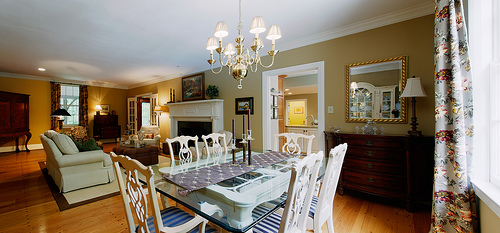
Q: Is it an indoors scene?
A: Yes, it is indoors.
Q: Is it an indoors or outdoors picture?
A: It is indoors.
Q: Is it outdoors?
A: No, it is indoors.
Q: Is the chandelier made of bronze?
A: Yes, the chandelier is made of bronze.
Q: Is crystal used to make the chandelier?
A: No, the chandelier is made of bronze.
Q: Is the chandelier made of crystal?
A: No, the chandelier is made of bronze.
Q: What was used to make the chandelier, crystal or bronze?
A: The chandelier is made of bronze.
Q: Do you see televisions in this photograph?
A: No, there are no televisions.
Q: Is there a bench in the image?
A: No, there are no benches.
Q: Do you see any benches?
A: No, there are no benches.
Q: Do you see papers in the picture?
A: No, there are no papers.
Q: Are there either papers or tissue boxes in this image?
A: No, there are no papers or tissue boxes.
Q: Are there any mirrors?
A: Yes, there is a mirror.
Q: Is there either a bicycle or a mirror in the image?
A: Yes, there is a mirror.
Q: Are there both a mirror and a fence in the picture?
A: No, there is a mirror but no fences.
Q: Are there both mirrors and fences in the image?
A: No, there is a mirror but no fences.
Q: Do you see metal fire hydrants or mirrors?
A: Yes, there is a metal mirror.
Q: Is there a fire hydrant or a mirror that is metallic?
A: Yes, the mirror is metallic.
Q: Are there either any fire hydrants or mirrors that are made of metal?
A: Yes, the mirror is made of metal.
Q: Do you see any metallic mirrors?
A: Yes, there is a metal mirror.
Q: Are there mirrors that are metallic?
A: Yes, there is a mirror that is metallic.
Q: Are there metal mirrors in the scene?
A: Yes, there is a mirror that is made of metal.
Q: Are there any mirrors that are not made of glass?
A: Yes, there is a mirror that is made of metal.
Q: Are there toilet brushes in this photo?
A: No, there are no toilet brushes.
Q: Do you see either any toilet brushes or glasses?
A: No, there are no toilet brushes or glasses.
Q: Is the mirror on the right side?
A: Yes, the mirror is on the right of the image.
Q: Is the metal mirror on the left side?
A: No, the mirror is on the right of the image.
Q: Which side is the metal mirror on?
A: The mirror is on the right of the image.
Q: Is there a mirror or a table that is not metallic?
A: No, there is a mirror but it is metallic.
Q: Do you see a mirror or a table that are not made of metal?
A: No, there is a mirror but it is made of metal.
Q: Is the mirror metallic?
A: Yes, the mirror is metallic.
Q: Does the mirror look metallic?
A: Yes, the mirror is metallic.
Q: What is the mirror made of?
A: The mirror is made of metal.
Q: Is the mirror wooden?
A: No, the mirror is metallic.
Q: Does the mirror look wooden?
A: No, the mirror is metallic.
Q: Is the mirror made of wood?
A: No, the mirror is made of metal.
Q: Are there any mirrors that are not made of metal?
A: No, there is a mirror but it is made of metal.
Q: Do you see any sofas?
A: Yes, there is a sofa.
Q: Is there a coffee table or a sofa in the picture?
A: Yes, there is a sofa.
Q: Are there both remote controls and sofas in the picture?
A: No, there is a sofa but no remote controls.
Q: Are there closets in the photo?
A: No, there are no closets.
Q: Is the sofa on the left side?
A: Yes, the sofa is on the left of the image.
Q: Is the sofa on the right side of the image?
A: No, the sofa is on the left of the image.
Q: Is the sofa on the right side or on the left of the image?
A: The sofa is on the left of the image.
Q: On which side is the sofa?
A: The sofa is on the left of the image.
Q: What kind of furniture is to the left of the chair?
A: The piece of furniture is a sofa.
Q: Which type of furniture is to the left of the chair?
A: The piece of furniture is a sofa.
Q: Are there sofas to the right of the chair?
A: No, the sofa is to the left of the chair.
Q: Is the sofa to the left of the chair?
A: Yes, the sofa is to the left of the chair.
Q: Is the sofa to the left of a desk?
A: No, the sofa is to the left of the chair.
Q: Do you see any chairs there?
A: Yes, there is a chair.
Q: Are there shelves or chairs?
A: Yes, there is a chair.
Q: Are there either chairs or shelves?
A: Yes, there is a chair.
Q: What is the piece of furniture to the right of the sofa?
A: The piece of furniture is a chair.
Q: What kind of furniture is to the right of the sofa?
A: The piece of furniture is a chair.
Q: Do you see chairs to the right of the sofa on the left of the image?
A: Yes, there is a chair to the right of the sofa.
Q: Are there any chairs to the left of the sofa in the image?
A: No, the chair is to the right of the sofa.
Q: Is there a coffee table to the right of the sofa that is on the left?
A: No, there is a chair to the right of the sofa.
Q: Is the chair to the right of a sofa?
A: Yes, the chair is to the right of a sofa.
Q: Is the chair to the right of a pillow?
A: No, the chair is to the right of a sofa.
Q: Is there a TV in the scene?
A: No, there are no televisions.